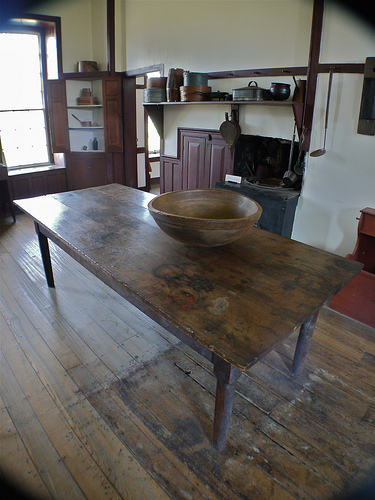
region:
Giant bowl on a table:
[146, 188, 264, 246]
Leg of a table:
[212, 353, 237, 452]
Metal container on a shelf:
[233, 81, 269, 100]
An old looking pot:
[75, 60, 99, 72]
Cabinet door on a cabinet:
[102, 76, 123, 152]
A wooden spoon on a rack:
[310, 68, 332, 158]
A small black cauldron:
[270, 81, 291, 100]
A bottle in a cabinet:
[92, 136, 100, 149]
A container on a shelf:
[143, 86, 166, 103]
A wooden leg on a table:
[30, 220, 54, 288]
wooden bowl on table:
[150, 177, 256, 249]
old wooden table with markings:
[0, 210, 332, 426]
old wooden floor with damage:
[34, 310, 351, 469]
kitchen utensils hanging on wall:
[278, 62, 343, 189]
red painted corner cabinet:
[64, 59, 131, 186]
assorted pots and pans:
[140, 67, 288, 106]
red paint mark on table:
[171, 296, 203, 315]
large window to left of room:
[12, 63, 51, 175]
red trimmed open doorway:
[121, 68, 167, 192]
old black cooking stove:
[230, 133, 281, 235]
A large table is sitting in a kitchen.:
[9, 180, 368, 459]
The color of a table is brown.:
[8, 179, 368, 454]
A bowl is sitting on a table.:
[144, 183, 266, 249]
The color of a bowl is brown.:
[145, 185, 266, 252]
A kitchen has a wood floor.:
[1, 178, 374, 499]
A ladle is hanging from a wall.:
[305, 58, 335, 162]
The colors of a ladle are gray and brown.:
[305, 63, 335, 163]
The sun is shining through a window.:
[0, 13, 71, 179]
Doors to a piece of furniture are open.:
[36, 58, 123, 194]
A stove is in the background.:
[210, 124, 308, 242]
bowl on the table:
[142, 167, 274, 254]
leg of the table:
[188, 370, 258, 463]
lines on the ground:
[39, 373, 168, 455]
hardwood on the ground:
[38, 369, 164, 457]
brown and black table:
[158, 246, 263, 310]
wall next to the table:
[322, 136, 356, 182]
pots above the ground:
[132, 20, 306, 112]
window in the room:
[6, 20, 57, 164]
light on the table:
[28, 192, 70, 228]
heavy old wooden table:
[13, 182, 363, 451]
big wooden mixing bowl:
[147, 186, 263, 247]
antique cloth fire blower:
[218, 109, 241, 156]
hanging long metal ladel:
[308, 69, 334, 159]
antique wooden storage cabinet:
[45, 70, 125, 190]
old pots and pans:
[142, 67, 289, 99]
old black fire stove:
[205, 140, 306, 238]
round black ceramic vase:
[269, 82, 289, 100]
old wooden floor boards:
[0, 274, 372, 497]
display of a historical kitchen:
[0, 2, 372, 497]